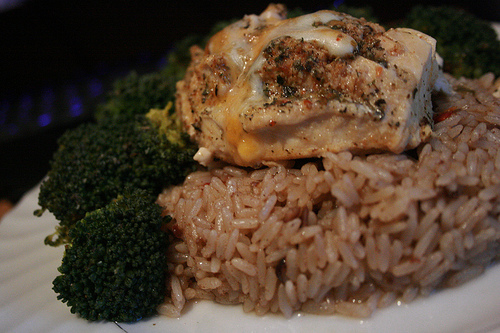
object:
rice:
[156, 70, 499, 318]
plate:
[1, 170, 499, 331]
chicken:
[173, 2, 441, 168]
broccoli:
[34, 3, 500, 324]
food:
[35, 4, 500, 322]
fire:
[0, 53, 166, 146]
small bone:
[192, 3, 288, 169]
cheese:
[196, 2, 360, 164]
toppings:
[178, 3, 453, 163]